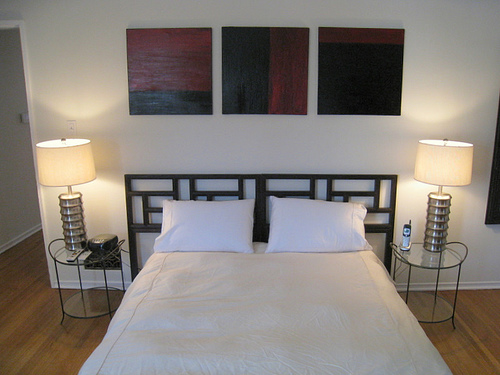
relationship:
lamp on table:
[36, 137, 99, 250] [47, 238, 126, 324]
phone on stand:
[404, 220, 412, 248] [403, 239, 415, 250]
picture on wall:
[126, 27, 211, 116] [1, 1, 498, 293]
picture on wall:
[221, 26, 311, 117] [1, 1, 498, 293]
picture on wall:
[319, 26, 405, 119] [1, 1, 498, 293]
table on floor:
[47, 238, 126, 324] [1, 228, 497, 374]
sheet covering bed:
[78, 242, 454, 372] [80, 172, 454, 373]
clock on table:
[88, 232, 119, 253] [47, 238, 126, 324]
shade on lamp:
[35, 137, 98, 187] [34, 135, 98, 187]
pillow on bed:
[153, 200, 255, 254] [80, 172, 454, 373]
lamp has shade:
[36, 137, 99, 250] [35, 137, 98, 187]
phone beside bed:
[404, 220, 412, 248] [80, 172, 454, 373]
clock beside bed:
[88, 232, 119, 253] [80, 172, 454, 373]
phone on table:
[404, 220, 412, 248] [386, 238, 469, 331]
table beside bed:
[47, 238, 126, 324] [80, 172, 454, 373]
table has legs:
[47, 238, 126, 324] [52, 260, 126, 325]